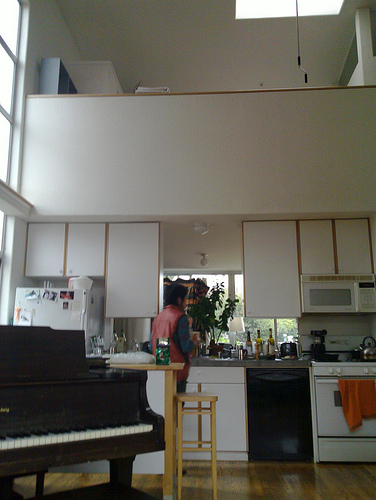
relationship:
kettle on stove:
[363, 330, 374, 360] [313, 342, 371, 376]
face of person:
[180, 282, 192, 308] [154, 280, 198, 412]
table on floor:
[79, 322, 206, 447] [0, 458, 375, 498]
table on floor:
[79, 322, 206, 447] [53, 448, 327, 498]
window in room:
[2, 61, 36, 146] [0, 26, 368, 500]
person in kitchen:
[154, 280, 198, 412] [3, 212, 349, 481]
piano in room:
[2, 297, 162, 462] [0, 26, 368, 500]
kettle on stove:
[357, 334, 376, 364] [313, 342, 371, 376]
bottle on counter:
[152, 331, 185, 372] [93, 338, 166, 393]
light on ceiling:
[256, 2, 319, 47] [158, 30, 224, 97]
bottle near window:
[152, 331, 185, 372] [245, 309, 303, 363]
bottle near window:
[266, 324, 275, 359] [245, 309, 303, 363]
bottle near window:
[249, 316, 270, 368] [245, 309, 303, 363]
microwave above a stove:
[242, 265, 370, 364] [303, 349, 365, 408]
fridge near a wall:
[17, 271, 108, 396] [9, 232, 28, 277]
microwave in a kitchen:
[242, 265, 370, 364] [24, 122, 360, 489]